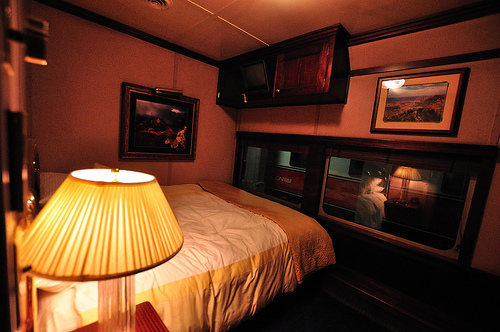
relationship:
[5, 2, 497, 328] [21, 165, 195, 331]
bedroom has lamp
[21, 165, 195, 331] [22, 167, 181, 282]
lamp has shade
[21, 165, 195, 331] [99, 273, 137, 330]
lamp has pedestal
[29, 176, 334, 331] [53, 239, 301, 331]
comforter has hem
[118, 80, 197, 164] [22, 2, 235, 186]
picture hanging on wall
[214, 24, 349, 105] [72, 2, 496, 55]
cabinet hanging from ceiling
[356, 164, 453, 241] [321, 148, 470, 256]
reflection in window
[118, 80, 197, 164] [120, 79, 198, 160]
picture has frame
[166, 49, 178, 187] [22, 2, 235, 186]
seam on wall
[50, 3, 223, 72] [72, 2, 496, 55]
molding under ceiling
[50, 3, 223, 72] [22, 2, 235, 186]
molding above wall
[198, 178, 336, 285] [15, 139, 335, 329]
blanket at bottom of bed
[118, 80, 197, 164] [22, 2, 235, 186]
picture on wall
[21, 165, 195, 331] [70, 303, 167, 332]
lamp on side table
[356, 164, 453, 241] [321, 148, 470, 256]
reflection on window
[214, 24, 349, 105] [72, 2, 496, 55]
cabinet on ceiling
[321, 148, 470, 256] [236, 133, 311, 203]
window next to window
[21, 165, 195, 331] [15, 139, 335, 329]
lamp next to bed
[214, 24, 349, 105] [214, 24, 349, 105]
cabinet next to cabinet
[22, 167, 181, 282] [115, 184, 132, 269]
shade has groove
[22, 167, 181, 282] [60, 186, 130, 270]
shade has groove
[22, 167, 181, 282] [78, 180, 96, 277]
shade has groove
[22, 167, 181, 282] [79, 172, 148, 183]
shade has light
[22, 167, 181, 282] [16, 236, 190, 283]
shade has base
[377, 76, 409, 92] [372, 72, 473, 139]
reflection on picture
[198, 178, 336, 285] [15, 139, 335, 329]
blanket on bed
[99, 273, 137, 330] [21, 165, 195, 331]
pedestal of lamp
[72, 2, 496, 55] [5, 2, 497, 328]
ceiling of bedroom